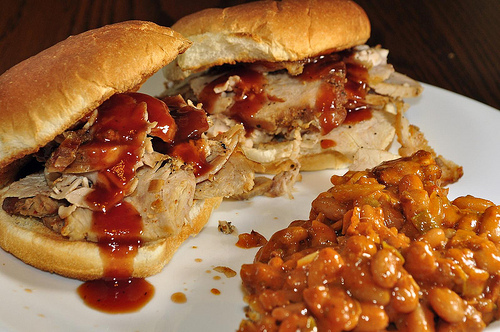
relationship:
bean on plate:
[243, 165, 493, 324] [1, 70, 499, 328]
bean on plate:
[398, 172, 432, 214] [1, 70, 499, 328]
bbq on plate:
[32, 67, 219, 317] [1, 70, 499, 328]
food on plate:
[0, 17, 500, 332] [1, 70, 499, 328]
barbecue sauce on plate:
[76, 135, 153, 313] [1, 70, 499, 328]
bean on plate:
[366, 247, 408, 290] [1, 70, 499, 328]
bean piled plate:
[366, 247, 408, 290] [1, 70, 499, 328]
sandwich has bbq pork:
[200, 63, 388, 157] [202, 72, 363, 118]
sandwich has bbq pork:
[14, 45, 226, 270] [51, 113, 209, 214]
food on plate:
[15, 22, 486, 314] [1, 70, 499, 328]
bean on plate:
[367, 241, 397, 281] [1, 70, 499, 328]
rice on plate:
[295, 194, 313, 211] [1, 70, 499, 328]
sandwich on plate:
[0, 19, 227, 284] [1, 70, 499, 328]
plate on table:
[1, 70, 499, 328] [5, 1, 497, 117]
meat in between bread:
[67, 50, 390, 225] [6, 0, 341, 122]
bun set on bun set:
[175, 5, 433, 186] [175, 5, 433, 186]